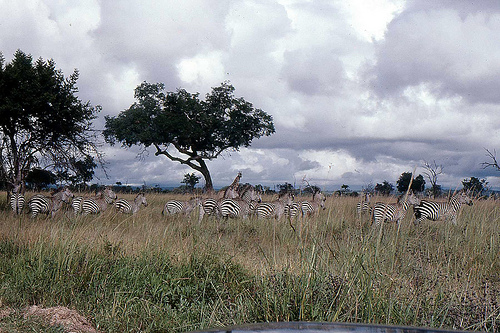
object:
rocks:
[0, 302, 102, 333]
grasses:
[9, 219, 495, 331]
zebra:
[288, 186, 326, 231]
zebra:
[361, 197, 443, 233]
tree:
[0, 47, 110, 197]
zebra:
[354, 192, 370, 220]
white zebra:
[114, 191, 148, 218]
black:
[118, 204, 124, 206]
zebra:
[215, 183, 261, 220]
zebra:
[198, 197, 220, 223]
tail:
[15, 198, 20, 214]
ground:
[388, 230, 480, 300]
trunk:
[151, 142, 230, 193]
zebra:
[219, 191, 262, 227]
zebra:
[81, 189, 119, 216]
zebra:
[8, 186, 26, 216]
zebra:
[413, 190, 473, 230]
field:
[0, 192, 500, 332]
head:
[457, 189, 474, 207]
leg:
[198, 211, 203, 225]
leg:
[214, 213, 221, 238]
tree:
[101, 79, 277, 193]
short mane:
[449, 189, 461, 201]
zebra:
[25, 186, 76, 221]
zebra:
[254, 191, 294, 221]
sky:
[1, 0, 500, 191]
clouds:
[241, 18, 457, 129]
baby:
[368, 188, 421, 230]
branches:
[0, 110, 111, 195]